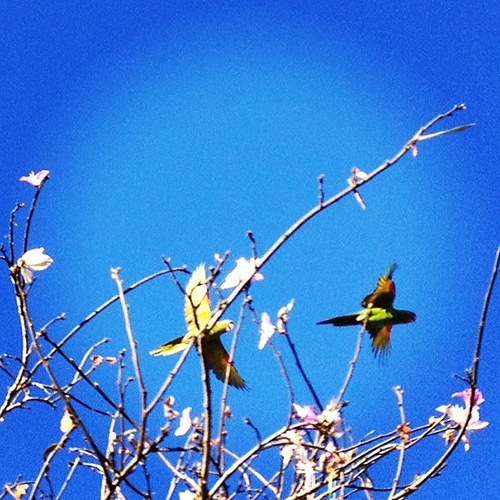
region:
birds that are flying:
[94, 193, 499, 464]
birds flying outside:
[158, 230, 485, 440]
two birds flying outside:
[77, 193, 482, 321]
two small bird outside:
[91, 218, 383, 419]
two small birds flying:
[72, 168, 481, 439]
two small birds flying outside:
[164, 244, 385, 365]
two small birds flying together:
[132, 188, 496, 407]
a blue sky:
[59, 32, 350, 260]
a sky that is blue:
[85, 89, 492, 219]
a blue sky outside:
[47, 90, 407, 230]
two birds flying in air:
[138, 241, 438, 397]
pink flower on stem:
[15, 167, 58, 202]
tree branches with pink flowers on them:
[3, 93, 498, 498]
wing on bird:
[357, 259, 414, 306]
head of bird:
[400, 305, 422, 327]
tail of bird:
[145, 329, 200, 361]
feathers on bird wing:
[363, 328, 410, 370]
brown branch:
[158, 257, 229, 497]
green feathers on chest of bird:
[361, 310, 396, 323]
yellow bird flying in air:
[126, 257, 255, 399]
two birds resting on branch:
[131, 237, 468, 412]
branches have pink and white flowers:
[5, 229, 499, 483]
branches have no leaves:
[9, 213, 499, 483]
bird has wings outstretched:
[169, 254, 259, 406]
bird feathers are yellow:
[116, 242, 287, 397]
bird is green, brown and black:
[319, 251, 430, 378]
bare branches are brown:
[11, 213, 494, 495]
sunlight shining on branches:
[11, 217, 498, 495]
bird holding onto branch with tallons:
[326, 249, 425, 389]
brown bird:
[325, 255, 431, 355]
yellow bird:
[143, 253, 244, 389]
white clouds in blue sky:
[193, 30, 232, 73]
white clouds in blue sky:
[411, 209, 443, 223]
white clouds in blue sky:
[115, 101, 167, 136]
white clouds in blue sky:
[38, 51, 113, 113]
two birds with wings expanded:
[145, 239, 432, 415]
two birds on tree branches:
[97, 237, 438, 421]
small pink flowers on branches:
[427, 375, 497, 457]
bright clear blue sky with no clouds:
[47, 157, 194, 217]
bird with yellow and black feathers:
[313, 263, 425, 360]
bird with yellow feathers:
[136, 259, 263, 392]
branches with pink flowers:
[17, 154, 474, 490]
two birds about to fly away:
[135, 237, 431, 412]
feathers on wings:
[360, 329, 400, 372]